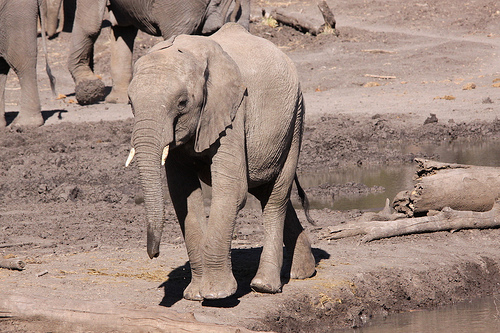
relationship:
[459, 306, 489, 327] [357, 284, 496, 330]
ripple on water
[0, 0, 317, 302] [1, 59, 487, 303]
elephant on ground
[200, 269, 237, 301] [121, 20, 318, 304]
foot of elephant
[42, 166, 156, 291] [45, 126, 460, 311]
dirt on ground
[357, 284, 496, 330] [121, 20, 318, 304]
water behind elephant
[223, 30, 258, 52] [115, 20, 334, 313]
back of elephant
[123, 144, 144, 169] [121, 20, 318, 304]
tusk of elephant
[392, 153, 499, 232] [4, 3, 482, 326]
log on ground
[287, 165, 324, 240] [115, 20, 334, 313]
tail of elephant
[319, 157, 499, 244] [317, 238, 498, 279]
log on ground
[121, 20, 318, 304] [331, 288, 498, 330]
elephant next to water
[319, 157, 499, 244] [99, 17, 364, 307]
log behind elephant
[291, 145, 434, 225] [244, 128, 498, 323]
water in a holes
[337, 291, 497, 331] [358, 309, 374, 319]
water in a holes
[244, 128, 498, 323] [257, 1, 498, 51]
holes in dirt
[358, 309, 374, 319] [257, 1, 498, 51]
holes in dirt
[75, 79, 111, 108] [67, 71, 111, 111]
mud on hoof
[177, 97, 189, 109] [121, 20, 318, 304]
eye on elephant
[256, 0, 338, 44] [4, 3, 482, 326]
rock on ground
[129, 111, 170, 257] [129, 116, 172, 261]
trunk of elephant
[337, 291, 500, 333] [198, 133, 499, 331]
water in watering hole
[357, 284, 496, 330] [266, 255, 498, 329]
water in watering hole